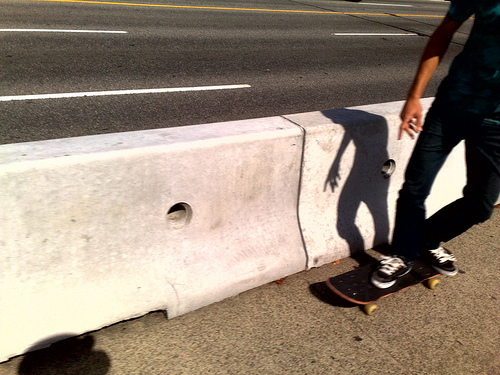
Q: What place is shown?
A: It is a street.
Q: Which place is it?
A: It is a street.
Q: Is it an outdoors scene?
A: Yes, it is outdoors.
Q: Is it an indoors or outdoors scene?
A: It is outdoors.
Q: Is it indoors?
A: No, it is outdoors.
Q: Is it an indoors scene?
A: No, it is outdoors.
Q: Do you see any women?
A: No, there are no women.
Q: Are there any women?
A: No, there are no women.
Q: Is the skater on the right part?
A: Yes, the skater is on the right of the image.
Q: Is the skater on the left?
A: No, the skater is on the right of the image.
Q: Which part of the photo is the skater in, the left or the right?
A: The skater is on the right of the image.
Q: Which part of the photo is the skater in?
A: The skater is on the right of the image.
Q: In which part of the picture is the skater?
A: The skater is on the right of the image.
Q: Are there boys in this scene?
A: No, there are no boys.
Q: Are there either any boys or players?
A: No, there are no boys or players.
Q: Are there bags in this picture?
A: No, there are no bags.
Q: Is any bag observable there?
A: No, there are no bags.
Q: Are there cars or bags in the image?
A: No, there are no bags or cars.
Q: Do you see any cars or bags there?
A: No, there are no bags or cars.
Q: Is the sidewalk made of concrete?
A: Yes, the sidewalk is made of concrete.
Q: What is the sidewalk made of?
A: The sidewalk is made of cement.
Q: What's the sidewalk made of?
A: The sidewalk is made of concrete.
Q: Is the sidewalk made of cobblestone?
A: No, the sidewalk is made of cement.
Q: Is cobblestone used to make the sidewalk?
A: No, the sidewalk is made of cement.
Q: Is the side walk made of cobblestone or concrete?
A: The side walk is made of concrete.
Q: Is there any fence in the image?
A: No, there are no fences.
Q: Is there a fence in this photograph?
A: No, there are no fences.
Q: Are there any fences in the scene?
A: No, there are no fences.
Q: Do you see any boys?
A: No, there are no boys.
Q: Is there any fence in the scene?
A: No, there are no fences.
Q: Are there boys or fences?
A: No, there are no fences or boys.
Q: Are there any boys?
A: No, there are no boys.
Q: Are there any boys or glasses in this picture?
A: No, there are no boys or glasses.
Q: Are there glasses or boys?
A: No, there are no boys or glasses.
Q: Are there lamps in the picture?
A: No, there are no lamps.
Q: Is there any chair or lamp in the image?
A: No, there are no lamps or chairs.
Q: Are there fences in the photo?
A: No, there are no fences.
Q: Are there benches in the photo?
A: No, there are no benches.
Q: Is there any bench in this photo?
A: No, there are no benches.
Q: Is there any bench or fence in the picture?
A: No, there are no benches or fences.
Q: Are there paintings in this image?
A: No, there are no paintings.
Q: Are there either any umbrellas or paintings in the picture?
A: No, there are no paintings or umbrellas.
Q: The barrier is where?
A: The barrier is on the street.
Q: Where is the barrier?
A: The barrier is on the street.